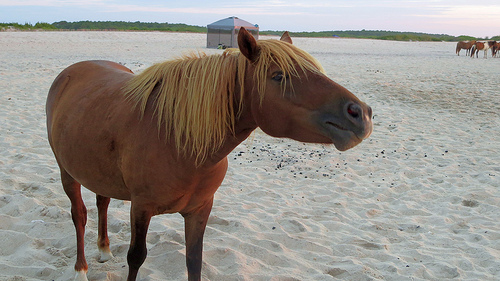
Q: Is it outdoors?
A: Yes, it is outdoors.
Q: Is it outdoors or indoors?
A: It is outdoors.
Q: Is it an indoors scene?
A: No, it is outdoors.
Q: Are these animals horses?
A: Yes, all the animals are horses.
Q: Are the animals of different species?
A: No, all the animals are horses.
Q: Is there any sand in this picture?
A: Yes, there is sand.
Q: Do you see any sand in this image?
A: Yes, there is sand.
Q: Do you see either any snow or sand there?
A: Yes, there is sand.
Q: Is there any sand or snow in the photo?
A: Yes, there is sand.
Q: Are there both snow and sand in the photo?
A: No, there is sand but no snow.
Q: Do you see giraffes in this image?
A: No, there are no giraffes.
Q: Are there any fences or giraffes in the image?
A: No, there are no giraffes or fences.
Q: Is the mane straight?
A: Yes, the mane is straight.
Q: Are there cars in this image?
A: No, there are no cars.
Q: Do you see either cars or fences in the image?
A: No, there are no cars or fences.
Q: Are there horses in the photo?
A: Yes, there are horses.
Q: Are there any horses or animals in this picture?
A: Yes, there are horses.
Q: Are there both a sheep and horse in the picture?
A: No, there are horses but no sheep.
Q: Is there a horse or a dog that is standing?
A: Yes, the horses are standing.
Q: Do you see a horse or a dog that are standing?
A: Yes, the horses are standing.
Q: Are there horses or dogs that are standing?
A: Yes, the horses are standing.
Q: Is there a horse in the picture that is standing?
A: Yes, there are horses that are standing.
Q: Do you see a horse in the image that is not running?
A: Yes, there are horses that are standing .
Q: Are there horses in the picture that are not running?
A: Yes, there are horses that are standing.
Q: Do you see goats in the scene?
A: No, there are no goats.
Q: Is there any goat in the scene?
A: No, there are no goats.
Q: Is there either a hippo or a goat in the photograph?
A: No, there are no goats or hippos.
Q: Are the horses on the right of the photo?
A: Yes, the horses are on the right of the image.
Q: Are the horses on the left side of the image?
A: No, the horses are on the right of the image.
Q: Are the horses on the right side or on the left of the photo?
A: The horses are on the right of the image.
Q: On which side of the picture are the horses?
A: The horses are on the right of the image.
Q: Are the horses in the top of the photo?
A: Yes, the horses are in the top of the image.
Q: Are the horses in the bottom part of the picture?
A: No, the horses are in the top of the image.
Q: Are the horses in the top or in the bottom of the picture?
A: The horses are in the top of the image.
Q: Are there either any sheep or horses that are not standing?
A: No, there are horses but they are standing.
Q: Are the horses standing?
A: Yes, the horses are standing.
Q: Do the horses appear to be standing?
A: Yes, the horses are standing.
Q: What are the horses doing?
A: The horses are standing.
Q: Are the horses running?
A: No, the horses are standing.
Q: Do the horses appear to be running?
A: No, the horses are standing.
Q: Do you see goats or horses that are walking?
A: No, there are horses but they are standing.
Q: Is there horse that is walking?
A: No, there are horses but they are standing.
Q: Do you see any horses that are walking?
A: No, there are horses but they are standing.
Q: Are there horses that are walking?
A: No, there are horses but they are standing.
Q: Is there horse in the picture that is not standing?
A: No, there are horses but they are standing.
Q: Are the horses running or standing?
A: The horses are standing.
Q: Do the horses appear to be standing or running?
A: The horses are standing.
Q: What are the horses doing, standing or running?
A: The horses are standing.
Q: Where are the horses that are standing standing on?
A: The horses are standing on the sand.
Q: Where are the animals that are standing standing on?
A: The horses are standing on the sand.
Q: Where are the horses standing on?
A: The horses are standing on the sand.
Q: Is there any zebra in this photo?
A: No, there are no zebras.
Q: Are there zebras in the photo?
A: No, there are no zebras.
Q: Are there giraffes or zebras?
A: No, there are no zebras or giraffes.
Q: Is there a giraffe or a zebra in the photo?
A: No, there are no zebras or giraffes.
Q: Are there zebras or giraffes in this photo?
A: No, there are no zebras or giraffes.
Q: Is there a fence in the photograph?
A: No, there are no fences.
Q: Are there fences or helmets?
A: No, there are no fences or helmets.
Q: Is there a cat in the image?
A: No, there are no cats.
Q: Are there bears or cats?
A: No, there are no cats or bears.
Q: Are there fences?
A: No, there are no fences.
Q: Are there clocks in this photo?
A: No, there are no clocks.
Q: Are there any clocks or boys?
A: No, there are no clocks or boys.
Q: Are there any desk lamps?
A: No, there are no desk lamps.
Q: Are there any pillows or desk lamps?
A: No, there are no desk lamps or pillows.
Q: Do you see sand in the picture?
A: Yes, there is sand.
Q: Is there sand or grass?
A: Yes, there is sand.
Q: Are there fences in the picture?
A: No, there are no fences.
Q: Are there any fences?
A: No, there are no fences.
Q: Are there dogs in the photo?
A: No, there are no dogs.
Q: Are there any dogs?
A: No, there are no dogs.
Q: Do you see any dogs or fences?
A: No, there are no dogs or fences.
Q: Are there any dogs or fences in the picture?
A: No, there are no dogs or fences.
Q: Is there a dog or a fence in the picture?
A: No, there are no dogs or fences.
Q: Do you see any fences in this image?
A: No, there are no fences.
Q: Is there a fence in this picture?
A: No, there are no fences.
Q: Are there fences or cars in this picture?
A: No, there are no fences or cars.